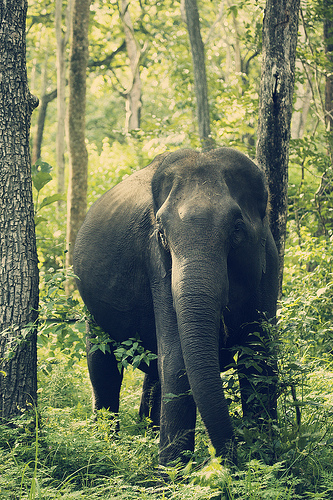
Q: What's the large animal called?
A: Elephant.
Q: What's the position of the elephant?
A: Standing.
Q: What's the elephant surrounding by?
A: Trees.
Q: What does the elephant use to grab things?
A: The trunk.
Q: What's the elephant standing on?
A: Grass.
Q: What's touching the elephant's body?
A: Green leaves.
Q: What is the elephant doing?
A: Standing.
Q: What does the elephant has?
A: Ears.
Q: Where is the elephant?
A: Woods.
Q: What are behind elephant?
A: Trees.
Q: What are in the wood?
A: Grass.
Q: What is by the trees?
A: Many green leaves.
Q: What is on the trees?
A: Plenty of trees.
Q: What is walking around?
A: An elephant.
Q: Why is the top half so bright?
A: From the daylight.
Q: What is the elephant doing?
A: Walking.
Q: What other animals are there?
A: Just the one.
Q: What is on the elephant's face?
A: A trunk.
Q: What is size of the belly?
A: Big and round.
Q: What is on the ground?
A: Grass and weeds.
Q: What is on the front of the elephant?
A: Trunk.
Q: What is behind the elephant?
A: Tree.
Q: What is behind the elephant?
A: Bushes and trees.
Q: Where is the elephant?
A: In woods.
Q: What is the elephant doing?
A: Walking.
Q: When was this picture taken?
A: During the day.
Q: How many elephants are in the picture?
A: One.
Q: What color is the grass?
A: Green.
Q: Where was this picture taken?
A: In a forest.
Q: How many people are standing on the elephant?
A: Zero.